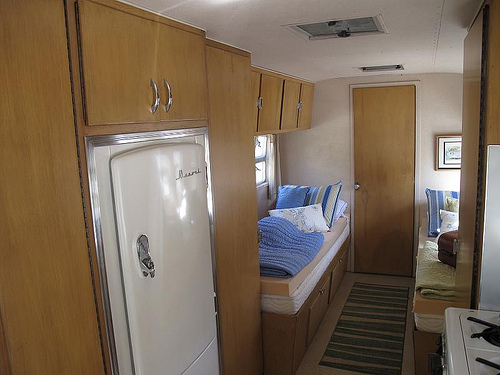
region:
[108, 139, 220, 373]
a white refrigerator door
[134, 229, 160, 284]
the handle to a refrigerator door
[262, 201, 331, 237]
a pillow on a bed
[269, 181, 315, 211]
a blue pillow on a bed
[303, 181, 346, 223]
a striped pillow on a bed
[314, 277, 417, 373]
a rug on a floor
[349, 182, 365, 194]
a knob to a door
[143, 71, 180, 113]
handles to cabinet doors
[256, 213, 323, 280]
a folded blue blanket on a bed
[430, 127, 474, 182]
a framed picture on a wall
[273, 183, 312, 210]
A light blue pillow on a bed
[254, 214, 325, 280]
A light blue blanket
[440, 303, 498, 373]
A white stove in a mini kitchen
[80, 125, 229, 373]
A white refridgerator in a kitchen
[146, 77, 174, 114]
Two silver handles on cupboard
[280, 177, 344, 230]
A blue, yellow and dark blue pillow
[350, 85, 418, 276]
A light brown door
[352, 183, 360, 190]
A silver door handle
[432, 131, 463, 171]
A picture frame on a wall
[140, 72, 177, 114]
Two handles of cabinets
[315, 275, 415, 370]
A mat on the floor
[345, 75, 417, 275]
A brown wooden door is closed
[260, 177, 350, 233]
Pillows on a bed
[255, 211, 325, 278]
A blanket is blue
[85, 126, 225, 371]
The fridge is white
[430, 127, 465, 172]
A framed painting on the wall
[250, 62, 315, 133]
The cabinets are brown and wooden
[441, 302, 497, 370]
Burners on a white stove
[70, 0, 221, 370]
A fridge under the cabinets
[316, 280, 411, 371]
A mat is on the floor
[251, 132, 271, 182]
Dayling coming from a window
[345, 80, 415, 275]
A door is closed shut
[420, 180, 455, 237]
Pillows on a bed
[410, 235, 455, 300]
A blanket is folded on the bed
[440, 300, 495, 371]
Black burners on white stove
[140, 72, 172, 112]
Silver handles on cabinets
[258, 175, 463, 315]
Two beds across from each other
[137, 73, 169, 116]
Small metal door hendge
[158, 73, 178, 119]
Small metal door hendge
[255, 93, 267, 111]
Small metal door hendge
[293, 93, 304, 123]
Small metal door hendge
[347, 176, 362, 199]
Small metal door handke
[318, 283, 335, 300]
Small metal door hendge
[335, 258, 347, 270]
Small metal door hendge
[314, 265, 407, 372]
Small colorful floor mat